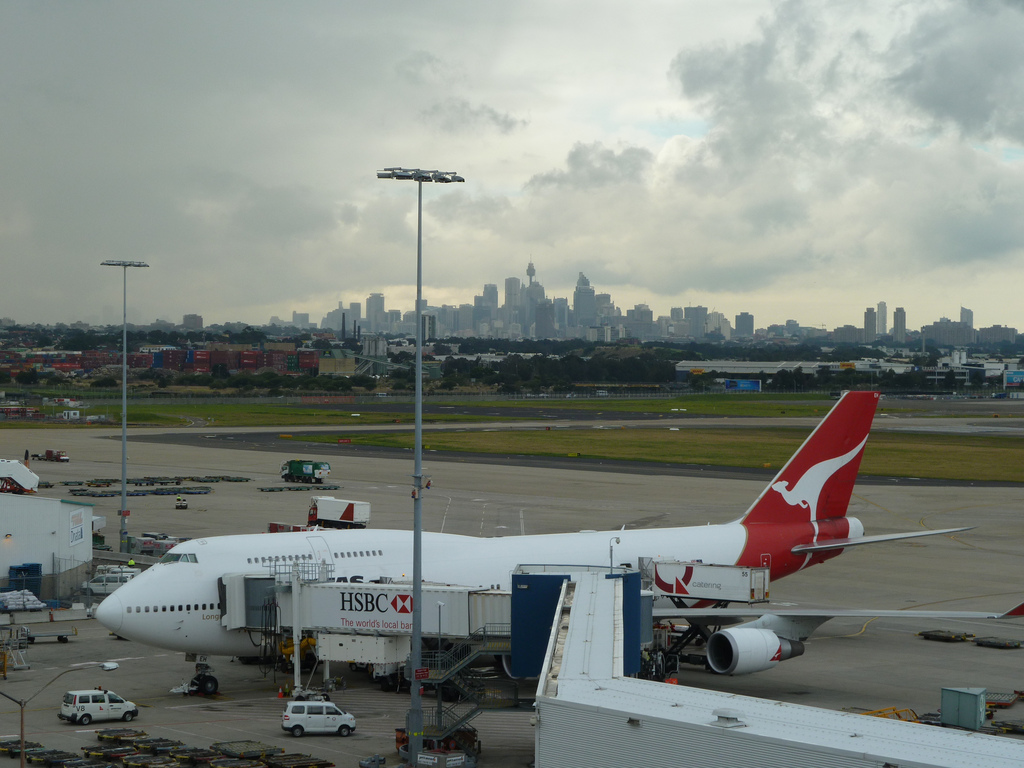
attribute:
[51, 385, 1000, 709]
airplane — big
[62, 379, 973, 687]
airplane — LAUGHING, big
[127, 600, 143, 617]
window — small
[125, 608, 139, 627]
window — small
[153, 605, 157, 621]
window — small